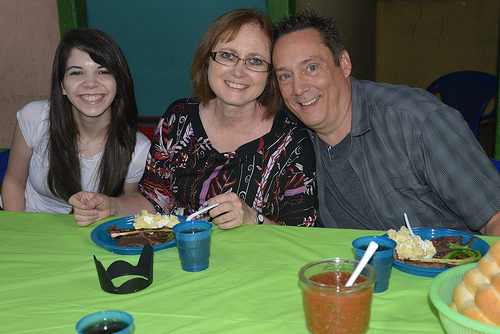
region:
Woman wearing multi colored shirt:
[140, 8, 316, 226]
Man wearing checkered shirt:
[270, 17, 498, 234]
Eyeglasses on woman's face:
[204, 44, 269, 76]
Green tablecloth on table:
[0, 209, 498, 330]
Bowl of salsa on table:
[295, 253, 377, 332]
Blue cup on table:
[172, 219, 214, 273]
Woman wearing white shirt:
[2, 29, 152, 214]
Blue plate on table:
[89, 211, 183, 252]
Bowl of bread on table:
[420, 243, 497, 332]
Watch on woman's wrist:
[254, 203, 266, 228]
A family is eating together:
[30, 16, 482, 322]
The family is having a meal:
[26, 28, 461, 299]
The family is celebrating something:
[13, 26, 466, 299]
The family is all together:
[12, 23, 482, 315]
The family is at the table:
[18, 20, 481, 298]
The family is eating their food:
[33, 20, 478, 317]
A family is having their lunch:
[17, 30, 492, 302]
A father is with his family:
[20, 16, 477, 296]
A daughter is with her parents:
[25, 13, 480, 308]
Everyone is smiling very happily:
[24, 10, 487, 298]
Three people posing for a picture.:
[15, 3, 490, 252]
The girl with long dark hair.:
[32, 26, 144, 206]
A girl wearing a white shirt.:
[5, 18, 142, 215]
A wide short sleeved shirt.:
[9, 89, 153, 216]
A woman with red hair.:
[191, 5, 276, 122]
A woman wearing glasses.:
[183, 19, 276, 114]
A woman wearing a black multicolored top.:
[141, 8, 314, 233]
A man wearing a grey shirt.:
[281, 21, 495, 230]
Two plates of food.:
[83, 179, 497, 278]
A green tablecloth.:
[4, 190, 485, 331]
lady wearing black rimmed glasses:
[197, 37, 286, 94]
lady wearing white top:
[8, 82, 160, 253]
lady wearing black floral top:
[142, 97, 337, 265]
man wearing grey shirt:
[295, 82, 498, 237]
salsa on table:
[291, 244, 396, 332]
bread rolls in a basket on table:
[440, 237, 499, 329]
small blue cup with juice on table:
[161, 215, 224, 272]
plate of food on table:
[77, 208, 204, 269]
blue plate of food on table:
[365, 219, 499, 300]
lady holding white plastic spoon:
[173, 175, 265, 261]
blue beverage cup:
[173, 219, 212, 270]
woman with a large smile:
[57, 33, 116, 137]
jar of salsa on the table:
[298, 259, 375, 331]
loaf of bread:
[451, 244, 498, 326]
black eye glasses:
[207, 49, 274, 72]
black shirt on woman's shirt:
[141, 99, 316, 229]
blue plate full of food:
[90, 213, 190, 251]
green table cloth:
[2, 209, 496, 331]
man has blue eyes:
[280, 65, 319, 82]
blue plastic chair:
[428, 69, 495, 136]